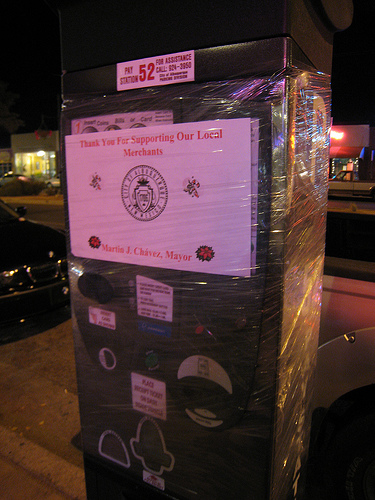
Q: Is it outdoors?
A: Yes, it is outdoors.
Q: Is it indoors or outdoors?
A: It is outdoors.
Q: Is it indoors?
A: No, it is outdoors.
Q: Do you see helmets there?
A: No, there are no helmets.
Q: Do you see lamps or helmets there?
A: No, there are no helmets or lamps.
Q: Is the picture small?
A: Yes, the picture is small.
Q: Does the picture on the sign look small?
A: Yes, the picture is small.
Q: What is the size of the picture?
A: The picture is small.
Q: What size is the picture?
A: The picture is small.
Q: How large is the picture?
A: The picture is small.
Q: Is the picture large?
A: No, the picture is small.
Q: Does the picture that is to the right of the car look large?
A: No, the picture is small.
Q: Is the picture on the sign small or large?
A: The picture is small.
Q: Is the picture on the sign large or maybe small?
A: The picture is small.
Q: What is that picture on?
A: The picture is on the sign.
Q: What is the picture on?
A: The picture is on the sign.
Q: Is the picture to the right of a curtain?
A: No, the picture is to the right of the car.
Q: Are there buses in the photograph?
A: No, there are no buses.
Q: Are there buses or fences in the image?
A: No, there are no buses or fences.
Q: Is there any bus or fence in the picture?
A: No, there are no buses or fences.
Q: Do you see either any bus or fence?
A: No, there are no buses or fences.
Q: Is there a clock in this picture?
A: No, there are no clocks.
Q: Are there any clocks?
A: No, there are no clocks.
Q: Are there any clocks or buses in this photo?
A: No, there are no clocks or buses.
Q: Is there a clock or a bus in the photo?
A: No, there are no clocks or buses.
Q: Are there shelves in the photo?
A: No, there are no shelves.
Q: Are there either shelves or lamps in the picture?
A: No, there are no shelves or lamps.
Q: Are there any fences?
A: No, there are no fences.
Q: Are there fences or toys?
A: No, there are no fences or toys.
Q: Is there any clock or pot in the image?
A: No, there are no clocks or pots.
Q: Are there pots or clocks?
A: No, there are no clocks or pots.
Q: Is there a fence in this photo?
A: No, there are no fences.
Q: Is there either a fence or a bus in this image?
A: No, there are no fences or buses.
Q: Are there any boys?
A: No, there are no boys.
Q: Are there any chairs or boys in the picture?
A: No, there are no boys or chairs.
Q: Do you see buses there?
A: No, there are no buses.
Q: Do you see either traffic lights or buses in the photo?
A: No, there are no buses or traffic lights.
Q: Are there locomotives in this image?
A: No, there are no locomotives.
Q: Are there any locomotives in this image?
A: No, there are no locomotives.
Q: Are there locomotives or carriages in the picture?
A: No, there are no locomotives or carriages.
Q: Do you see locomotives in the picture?
A: No, there are no locomotives.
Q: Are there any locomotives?
A: No, there are no locomotives.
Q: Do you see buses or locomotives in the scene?
A: No, there are no locomotives or buses.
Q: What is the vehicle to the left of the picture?
A: The vehicle is a car.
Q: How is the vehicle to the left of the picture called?
A: The vehicle is a car.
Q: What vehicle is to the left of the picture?
A: The vehicle is a car.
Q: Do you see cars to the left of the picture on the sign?
A: Yes, there is a car to the left of the picture.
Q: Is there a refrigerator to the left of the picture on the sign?
A: No, there is a car to the left of the picture.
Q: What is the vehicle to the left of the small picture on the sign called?
A: The vehicle is a car.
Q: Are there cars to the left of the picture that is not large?
A: Yes, there is a car to the left of the picture.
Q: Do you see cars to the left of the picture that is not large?
A: Yes, there is a car to the left of the picture.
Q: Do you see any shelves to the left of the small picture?
A: No, there is a car to the left of the picture.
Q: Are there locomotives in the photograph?
A: No, there are no locomotives.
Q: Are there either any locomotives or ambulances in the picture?
A: No, there are no locomotives or ambulances.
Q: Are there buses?
A: No, there are no buses.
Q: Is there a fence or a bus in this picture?
A: No, there are no buses or fences.